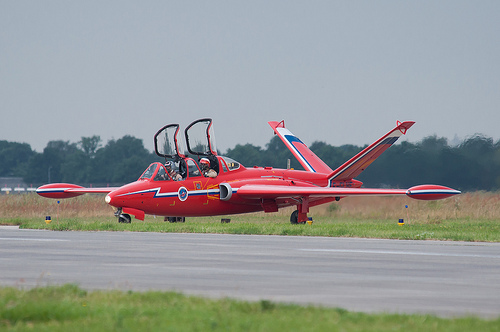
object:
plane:
[36, 118, 459, 224]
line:
[156, 189, 220, 196]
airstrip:
[0, 239, 69, 242]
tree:
[99, 135, 145, 181]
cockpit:
[137, 124, 179, 181]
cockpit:
[186, 118, 217, 178]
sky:
[0, 0, 499, 118]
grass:
[0, 284, 499, 331]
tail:
[267, 121, 416, 179]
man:
[165, 161, 182, 181]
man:
[200, 157, 217, 177]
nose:
[104, 185, 130, 207]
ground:
[0, 224, 499, 332]